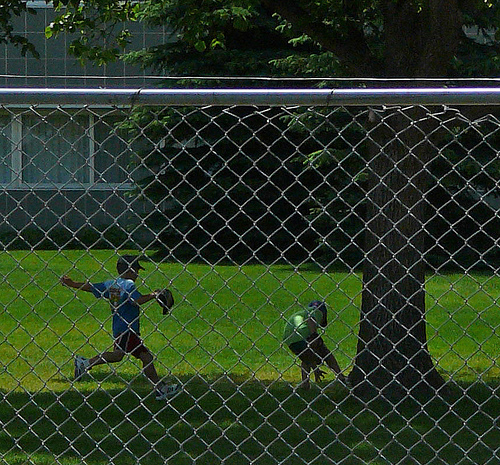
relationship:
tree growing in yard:
[256, 0, 449, 390] [0, 243, 489, 464]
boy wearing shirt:
[283, 299, 350, 389] [285, 307, 323, 343]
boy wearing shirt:
[61, 254, 177, 397] [94, 278, 141, 332]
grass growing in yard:
[0, 249, 493, 464] [0, 243, 489, 464]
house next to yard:
[1, 3, 215, 244] [0, 243, 489, 464]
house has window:
[1, 3, 215, 244] [3, 116, 159, 184]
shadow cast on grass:
[0, 373, 499, 464] [0, 249, 493, 464]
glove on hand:
[158, 287, 175, 315] [152, 290, 165, 302]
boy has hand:
[61, 254, 177, 397] [152, 290, 165, 302]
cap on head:
[117, 255, 145, 268] [118, 257, 139, 282]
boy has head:
[61, 254, 177, 397] [118, 257, 139, 282]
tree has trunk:
[256, 0, 449, 390] [350, 79, 444, 383]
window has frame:
[3, 116, 159, 184] [1, 180, 170, 194]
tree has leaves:
[256, 0, 449, 390] [0, 1, 491, 80]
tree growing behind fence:
[256, 0, 449, 390] [1, 77, 498, 464]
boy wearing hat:
[283, 299, 350, 389] [309, 300, 329, 324]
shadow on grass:
[0, 373, 499, 464] [0, 249, 493, 464]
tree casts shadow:
[256, 0, 449, 390] [0, 373, 499, 464]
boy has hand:
[283, 299, 350, 389] [311, 367, 328, 384]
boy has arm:
[61, 254, 177, 397] [61, 274, 110, 294]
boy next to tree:
[283, 299, 350, 389] [256, 0, 449, 390]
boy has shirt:
[283, 299, 350, 389] [285, 307, 323, 343]